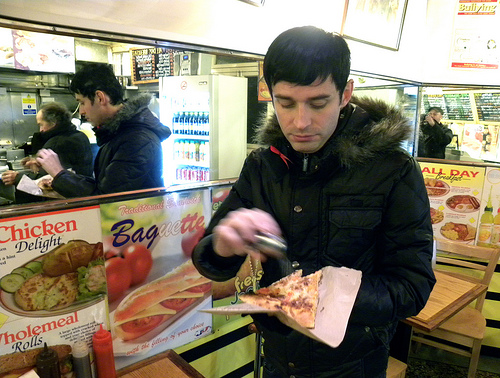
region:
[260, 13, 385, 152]
head of a person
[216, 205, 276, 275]
arm of a person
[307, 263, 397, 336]
arm of a person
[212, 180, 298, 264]
hand of a person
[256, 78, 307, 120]
eye of a person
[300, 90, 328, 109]
eye of a person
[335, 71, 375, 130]
an ear of a person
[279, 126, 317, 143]
mouth of a person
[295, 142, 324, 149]
jaw of a person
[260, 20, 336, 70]
hair of a person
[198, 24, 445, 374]
a man eating a pizza standing up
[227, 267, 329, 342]
a large slice of pizza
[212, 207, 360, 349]
a hand shaking spice onto a pizza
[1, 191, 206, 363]
food advertisements on the wall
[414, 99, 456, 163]
man taking a photo of someone eating pizza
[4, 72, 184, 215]
men eating pieces of pizza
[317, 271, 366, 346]
a brown napkin being held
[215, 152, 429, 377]
a black button up parka jacket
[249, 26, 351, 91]
a man's black hair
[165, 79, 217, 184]
a cooler full of drinks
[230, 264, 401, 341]
Pizza in the mans hand.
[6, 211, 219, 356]
The signs on the wall.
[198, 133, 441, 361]
The black hooded coat.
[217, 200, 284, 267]
The mans right hand.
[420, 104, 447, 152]
Man taking a photo in the back.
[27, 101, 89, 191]
Man in a black coat.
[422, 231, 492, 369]
The wooden chair.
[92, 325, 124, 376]
Bottle of ketchup on the table.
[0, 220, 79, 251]
The words Chicken Delight on the sign.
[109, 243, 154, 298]
Photo of two tomatoes.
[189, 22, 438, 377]
this is a man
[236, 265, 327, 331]
this is a slice of pizza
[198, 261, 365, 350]
this is a piece of paper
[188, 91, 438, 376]
this is a black jacket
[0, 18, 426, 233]
this is a long mirror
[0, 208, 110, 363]
a sign on the wall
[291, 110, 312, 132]
this is his nose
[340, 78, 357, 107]
that is his ear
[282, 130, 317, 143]
this is his mouth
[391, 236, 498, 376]
this is a chair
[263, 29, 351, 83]
the guy's black hair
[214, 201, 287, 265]
the man's right hand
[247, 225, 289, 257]
seasoning shaker in hand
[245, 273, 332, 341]
slice of pizza on paper towel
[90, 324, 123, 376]
ketchup in a bottle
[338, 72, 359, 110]
the man's left ear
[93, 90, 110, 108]
reflection of right ear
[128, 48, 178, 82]
menu of the restaurant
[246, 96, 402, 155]
fur on the hood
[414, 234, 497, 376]
wooden chair in the restaurant